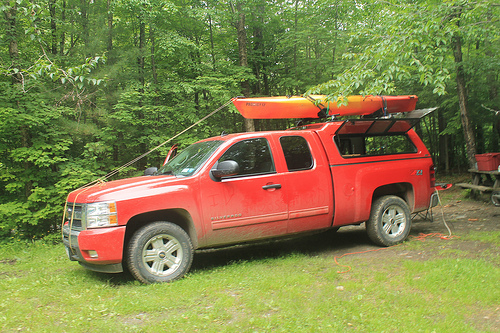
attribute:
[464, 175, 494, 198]
bench — wooden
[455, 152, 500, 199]
table — wooden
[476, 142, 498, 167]
bin — plastic, red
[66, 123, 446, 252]
truck — red, large, parked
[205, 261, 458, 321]
grass — green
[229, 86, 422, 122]
canoe — orange, bright, tied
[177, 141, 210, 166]
windshield — glass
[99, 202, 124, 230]
headlight — yellow, white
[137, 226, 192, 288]
tire — black, rubber, round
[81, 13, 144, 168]
tree — green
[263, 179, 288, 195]
handle — metal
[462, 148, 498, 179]
basket — red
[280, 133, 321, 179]
window — open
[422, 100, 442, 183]
door — open